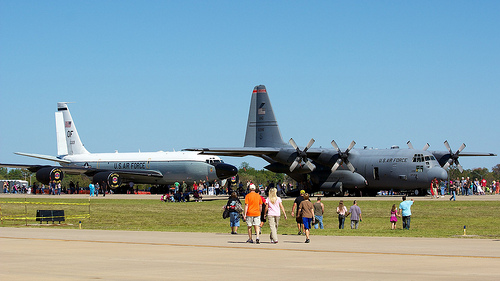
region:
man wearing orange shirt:
[237, 189, 273, 221]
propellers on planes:
[320, 132, 368, 176]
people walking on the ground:
[199, 170, 426, 248]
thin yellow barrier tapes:
[17, 184, 103, 233]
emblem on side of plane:
[53, 100, 92, 157]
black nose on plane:
[208, 157, 240, 182]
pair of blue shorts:
[296, 215, 328, 229]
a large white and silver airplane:
[14, 100, 239, 195]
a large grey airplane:
[178, 81, 499, 196]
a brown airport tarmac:
[1, 226, 498, 278]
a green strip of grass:
[1, 196, 499, 236]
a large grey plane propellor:
[286, 135, 316, 175]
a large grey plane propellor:
[329, 137, 357, 173]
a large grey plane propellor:
[406, 140, 431, 150]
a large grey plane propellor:
[443, 139, 468, 175]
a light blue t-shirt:
[398, 199, 414, 216]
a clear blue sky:
[0, 0, 499, 172]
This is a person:
[396, 190, 418, 235]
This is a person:
[385, 198, 402, 230]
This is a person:
[347, 196, 362, 233]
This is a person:
[332, 197, 349, 230]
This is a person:
[312, 193, 329, 229]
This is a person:
[298, 193, 315, 240]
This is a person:
[264, 183, 282, 249]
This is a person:
[241, 178, 261, 248]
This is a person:
[221, 187, 247, 239]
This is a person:
[445, 179, 462, 206]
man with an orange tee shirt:
[243, 184, 267, 241]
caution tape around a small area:
[1, 197, 93, 225]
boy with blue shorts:
[297, 191, 317, 246]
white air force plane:
[17, 96, 237, 200]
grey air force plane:
[185, 76, 498, 201]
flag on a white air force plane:
[63, 120, 73, 128]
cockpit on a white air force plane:
[202, 153, 222, 168]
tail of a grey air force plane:
[241, 82, 285, 142]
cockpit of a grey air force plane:
[407, 153, 436, 166]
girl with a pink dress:
[389, 201, 398, 227]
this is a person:
[395, 186, 433, 243]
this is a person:
[378, 204, 414, 246]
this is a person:
[344, 187, 374, 247]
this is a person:
[327, 190, 350, 246]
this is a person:
[297, 181, 322, 254]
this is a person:
[254, 186, 296, 266]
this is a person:
[241, 181, 268, 257]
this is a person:
[214, 188, 250, 246]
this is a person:
[184, 174, 205, 206]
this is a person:
[439, 168, 459, 202]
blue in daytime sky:
[1, 1, 497, 170]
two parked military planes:
[1, 84, 492, 196]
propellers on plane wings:
[203, 139, 491, 177]